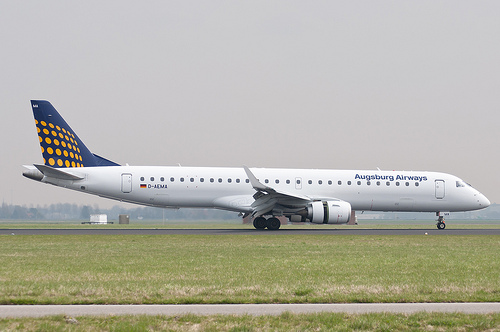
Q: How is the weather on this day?
A: It is overcast.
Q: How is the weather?
A: It is overcast.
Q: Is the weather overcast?
A: Yes, it is overcast.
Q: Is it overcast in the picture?
A: Yes, it is overcast.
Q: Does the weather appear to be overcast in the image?
A: Yes, it is overcast.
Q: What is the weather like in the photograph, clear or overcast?
A: It is overcast.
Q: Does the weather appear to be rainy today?
A: No, it is overcast.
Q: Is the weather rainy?
A: No, it is overcast.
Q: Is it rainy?
A: No, it is overcast.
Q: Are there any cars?
A: No, there are no cars.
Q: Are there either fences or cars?
A: No, there are no cars or fences.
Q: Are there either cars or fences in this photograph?
A: No, there are no cars or fences.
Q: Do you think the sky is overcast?
A: Yes, the sky is overcast.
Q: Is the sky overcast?
A: Yes, the sky is overcast.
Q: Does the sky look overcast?
A: Yes, the sky is overcast.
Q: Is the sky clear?
A: No, the sky is overcast.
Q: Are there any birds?
A: No, there are no birds.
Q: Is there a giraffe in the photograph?
A: No, there are no giraffes.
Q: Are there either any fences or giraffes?
A: No, there are no giraffes or fences.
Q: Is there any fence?
A: No, there are no fences.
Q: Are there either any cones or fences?
A: No, there are no fences or cones.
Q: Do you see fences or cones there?
A: No, there are no fences or cones.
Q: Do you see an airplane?
A: Yes, there is an airplane.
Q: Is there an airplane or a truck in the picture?
A: Yes, there is an airplane.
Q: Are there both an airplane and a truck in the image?
A: No, there is an airplane but no trucks.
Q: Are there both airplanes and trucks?
A: No, there is an airplane but no trucks.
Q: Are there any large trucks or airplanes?
A: Yes, there is a large airplane.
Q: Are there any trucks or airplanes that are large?
A: Yes, the airplane is large.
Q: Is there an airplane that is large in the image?
A: Yes, there is a large airplane.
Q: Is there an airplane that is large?
A: Yes, there is an airplane that is large.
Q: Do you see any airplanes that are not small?
A: Yes, there is a large airplane.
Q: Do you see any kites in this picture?
A: No, there are no kites.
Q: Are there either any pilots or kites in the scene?
A: No, there are no kites or pilots.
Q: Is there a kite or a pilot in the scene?
A: No, there are no kites or pilots.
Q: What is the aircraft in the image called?
A: The aircraft is an airplane.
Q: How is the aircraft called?
A: The aircraft is an airplane.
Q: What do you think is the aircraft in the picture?
A: The aircraft is an airplane.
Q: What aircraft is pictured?
A: The aircraft is an airplane.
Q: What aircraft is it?
A: The aircraft is an airplane.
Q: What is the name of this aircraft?
A: This is an airplane.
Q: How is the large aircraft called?
A: The aircraft is an airplane.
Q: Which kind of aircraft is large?
A: The aircraft is an airplane.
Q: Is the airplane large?
A: Yes, the airplane is large.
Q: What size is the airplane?
A: The airplane is large.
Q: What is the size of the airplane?
A: The airplane is large.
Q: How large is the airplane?
A: The airplane is large.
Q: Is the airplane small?
A: No, the airplane is large.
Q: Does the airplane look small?
A: No, the airplane is large.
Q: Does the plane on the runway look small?
A: No, the plane is large.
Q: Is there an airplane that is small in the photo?
A: No, there is an airplane but it is large.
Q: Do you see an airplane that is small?
A: No, there is an airplane but it is large.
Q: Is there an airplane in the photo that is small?
A: No, there is an airplane but it is large.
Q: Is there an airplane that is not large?
A: No, there is an airplane but it is large.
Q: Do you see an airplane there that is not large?
A: No, there is an airplane but it is large.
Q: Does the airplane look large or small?
A: The airplane is large.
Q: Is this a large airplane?
A: Yes, this is a large airplane.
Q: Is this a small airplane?
A: No, this is a large airplane.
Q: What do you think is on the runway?
A: The plane is on the runway.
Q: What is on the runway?
A: The plane is on the runway.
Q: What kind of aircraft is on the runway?
A: The aircraft is an airplane.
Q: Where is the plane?
A: The plane is on the runway.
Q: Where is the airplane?
A: The plane is on the runway.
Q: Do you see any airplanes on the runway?
A: Yes, there is an airplane on the runway.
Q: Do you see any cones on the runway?
A: No, there is an airplane on the runway.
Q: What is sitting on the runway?
A: The plane is sitting on the runway.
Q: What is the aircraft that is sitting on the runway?
A: The aircraft is an airplane.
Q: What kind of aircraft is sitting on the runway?
A: The aircraft is an airplane.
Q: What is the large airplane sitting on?
A: The plane is sitting on the runway.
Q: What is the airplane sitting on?
A: The plane is sitting on the runway.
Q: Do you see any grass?
A: Yes, there is grass.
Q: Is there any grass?
A: Yes, there is grass.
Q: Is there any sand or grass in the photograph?
A: Yes, there is grass.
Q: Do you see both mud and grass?
A: No, there is grass but no mud.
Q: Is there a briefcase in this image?
A: No, there are no briefcases.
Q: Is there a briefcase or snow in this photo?
A: No, there are no briefcases or snow.